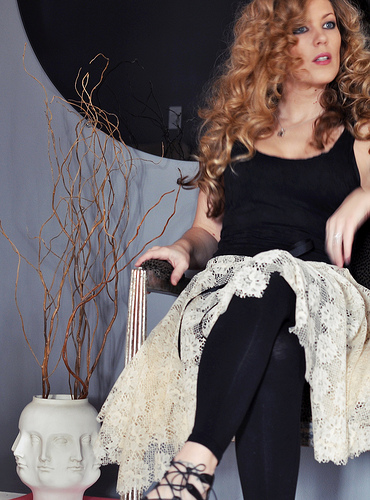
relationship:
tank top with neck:
[200, 103, 364, 267] [253, 122, 344, 161]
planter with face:
[10, 393, 104, 498] [54, 425, 92, 485]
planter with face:
[10, 393, 104, 498] [31, 429, 66, 486]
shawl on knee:
[94, 246, 369, 499] [236, 270, 297, 317]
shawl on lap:
[94, 246, 369, 499] [187, 247, 368, 355]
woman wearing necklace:
[134, 21, 368, 498] [273, 112, 321, 138]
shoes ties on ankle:
[147, 461, 218, 497] [170, 443, 216, 491]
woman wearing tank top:
[134, 21, 368, 498] [208, 120, 360, 263]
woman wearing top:
[221, 128, 360, 258] [140, 2, 360, 496]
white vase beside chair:
[6, 389, 104, 498] [124, 251, 191, 362]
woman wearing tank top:
[134, 21, 368, 498] [200, 103, 364, 267]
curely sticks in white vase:
[27, 76, 108, 395] [6, 389, 104, 498]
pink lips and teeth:
[312, 52, 342, 68] [317, 55, 329, 63]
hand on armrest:
[133, 244, 190, 285] [116, 256, 234, 360]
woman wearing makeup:
[146, 4, 369, 302] [293, 18, 333, 36]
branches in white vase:
[24, 44, 200, 405] [6, 389, 104, 498]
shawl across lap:
[94, 246, 369, 499] [187, 247, 368, 355]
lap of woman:
[187, 247, 368, 355] [134, 21, 368, 498]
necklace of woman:
[270, 122, 289, 141] [221, 128, 360, 258]